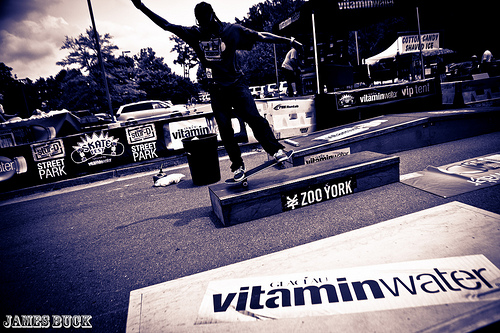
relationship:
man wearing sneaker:
[130, 0, 307, 189] [268, 146, 288, 168]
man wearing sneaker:
[130, 0, 307, 189] [227, 162, 249, 184]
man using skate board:
[130, 0, 307, 189] [224, 147, 293, 185]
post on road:
[83, 0, 118, 120] [1, 104, 494, 331]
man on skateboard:
[130, 0, 307, 189] [213, 148, 292, 179]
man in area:
[130, 0, 307, 189] [5, 3, 496, 330]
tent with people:
[301, 0, 401, 88] [278, 35, 303, 96]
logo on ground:
[218, 277, 400, 307] [268, 232, 344, 264]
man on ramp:
[129, 0, 335, 188] [206, 133, 406, 231]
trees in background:
[17, 21, 202, 113] [6, 0, 261, 125]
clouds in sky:
[5, 17, 86, 64] [3, 3, 249, 74]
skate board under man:
[224, 149, 297, 187] [130, 0, 307, 189]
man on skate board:
[130, 0, 307, 189] [224, 149, 297, 187]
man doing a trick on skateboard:
[130, 0, 307, 189] [223, 147, 297, 188]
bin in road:
[181, 133, 221, 187] [1, 104, 500, 331]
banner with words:
[24, 136, 76, 189] [36, 156, 66, 177]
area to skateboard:
[0, 0, 496, 331] [201, 126, 315, 204]